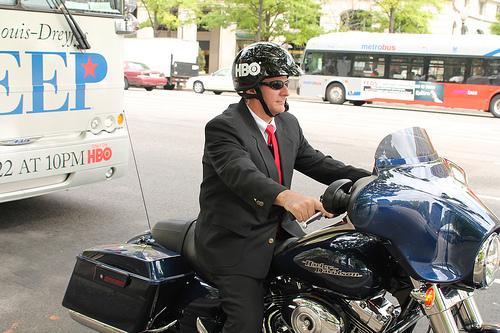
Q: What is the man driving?
A: Motorcycle.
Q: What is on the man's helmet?
A: HBO.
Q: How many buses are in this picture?
A: Two.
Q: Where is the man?
A: On a motorcycle.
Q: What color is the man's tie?
A: Red.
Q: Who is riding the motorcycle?
A: The man in the suit.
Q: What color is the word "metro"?
A: Blue.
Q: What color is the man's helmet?
A: Black.